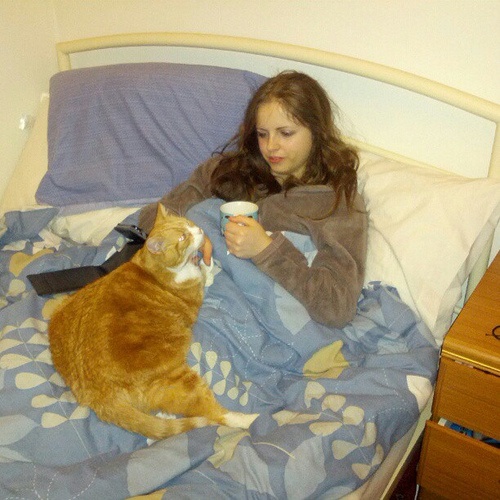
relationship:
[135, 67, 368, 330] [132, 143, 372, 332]
woman wearing top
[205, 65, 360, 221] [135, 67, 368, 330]
hair on woman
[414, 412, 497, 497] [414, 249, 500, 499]
drawer in cabinet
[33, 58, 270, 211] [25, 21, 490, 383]
pillow on bed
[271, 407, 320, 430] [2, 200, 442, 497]
design on comforter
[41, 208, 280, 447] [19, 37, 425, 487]
cat on bed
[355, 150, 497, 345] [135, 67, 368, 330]
pillow underneath woman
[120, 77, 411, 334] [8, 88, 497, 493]
woman laying in bed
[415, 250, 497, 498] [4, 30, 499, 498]
cabinet next to bed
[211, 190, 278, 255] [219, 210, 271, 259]
mug in hand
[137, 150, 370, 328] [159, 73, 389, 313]
sweater on woman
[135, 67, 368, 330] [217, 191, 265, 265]
woman holding cup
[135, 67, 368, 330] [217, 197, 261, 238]
woman with mug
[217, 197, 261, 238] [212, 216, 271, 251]
mug in hand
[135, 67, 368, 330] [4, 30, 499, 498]
woman in bed